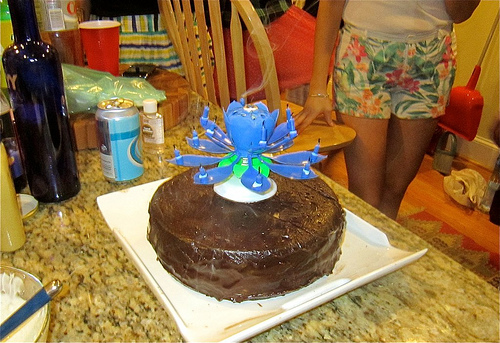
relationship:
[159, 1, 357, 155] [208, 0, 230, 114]
chair has spindle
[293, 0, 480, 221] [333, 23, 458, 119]
woman wearing shorts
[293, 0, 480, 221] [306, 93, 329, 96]
woman wearing bracelet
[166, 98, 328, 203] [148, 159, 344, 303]
topper on top of cake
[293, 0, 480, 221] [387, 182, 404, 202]
woman has knee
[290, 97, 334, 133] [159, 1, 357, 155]
hand on top of chair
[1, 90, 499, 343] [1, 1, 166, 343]
countertop has clutter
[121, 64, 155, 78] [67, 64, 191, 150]
cell phone on top of lazy susan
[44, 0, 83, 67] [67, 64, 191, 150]
bottle on top of lazy susan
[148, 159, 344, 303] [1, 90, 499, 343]
cake on top of table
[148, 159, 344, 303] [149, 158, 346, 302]
cake has frosting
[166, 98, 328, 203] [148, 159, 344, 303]
blue thing on top of cake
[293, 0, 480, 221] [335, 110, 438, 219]
person has legs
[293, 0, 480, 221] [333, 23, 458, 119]
person has shorts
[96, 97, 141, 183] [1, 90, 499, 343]
can on top of table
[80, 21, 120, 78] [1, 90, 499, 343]
cup on top of table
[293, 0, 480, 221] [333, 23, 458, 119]
lady wearing shorts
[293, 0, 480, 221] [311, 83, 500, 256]
lady on top of floor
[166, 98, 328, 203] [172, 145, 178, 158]
decoration has candle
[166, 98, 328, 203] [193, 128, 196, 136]
decoration has candle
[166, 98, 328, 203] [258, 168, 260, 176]
decoration has candle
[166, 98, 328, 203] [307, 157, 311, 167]
decoration has candle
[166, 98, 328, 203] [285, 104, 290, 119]
decoration has candle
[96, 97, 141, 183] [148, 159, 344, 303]
can next to cake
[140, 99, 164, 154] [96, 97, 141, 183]
bottle next to can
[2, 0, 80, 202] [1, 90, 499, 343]
wine on top of table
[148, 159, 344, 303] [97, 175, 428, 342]
cake on top of white container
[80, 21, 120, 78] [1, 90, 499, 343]
cup on top of countertop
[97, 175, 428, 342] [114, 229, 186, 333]
tray has edge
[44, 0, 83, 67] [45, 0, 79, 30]
bottle has part